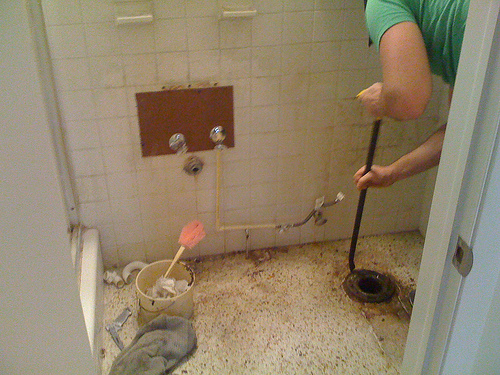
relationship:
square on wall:
[134, 85, 235, 159] [38, 0, 449, 287]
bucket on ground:
[134, 258, 197, 330] [103, 245, 413, 371]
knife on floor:
[105, 305, 132, 351] [99, 232, 441, 374]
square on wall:
[133, 85, 235, 156] [52, 1, 355, 239]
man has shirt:
[333, 3, 488, 92] [365, 0, 462, 79]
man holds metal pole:
[352, 0, 471, 190] [347, 119, 382, 274]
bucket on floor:
[131, 250, 259, 348] [32, 321, 302, 375]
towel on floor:
[121, 313, 209, 372] [150, 340, 229, 375]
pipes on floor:
[101, 257, 150, 289] [178, 343, 272, 375]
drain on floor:
[338, 264, 406, 308] [94, 232, 441, 373]